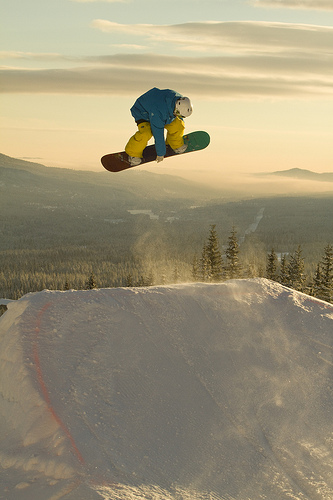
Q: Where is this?
A: This is at the path.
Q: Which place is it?
A: It is a path.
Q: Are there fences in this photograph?
A: No, there are no fences.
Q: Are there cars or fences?
A: No, there are no fences or cars.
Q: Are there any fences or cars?
A: No, there are no fences or cars.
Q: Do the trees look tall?
A: Yes, the trees are tall.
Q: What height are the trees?
A: The trees are tall.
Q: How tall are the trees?
A: The trees are tall.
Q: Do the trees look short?
A: No, the trees are tall.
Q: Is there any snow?
A: Yes, there is snow.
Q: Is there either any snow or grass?
A: Yes, there is snow.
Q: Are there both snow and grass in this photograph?
A: No, there is snow but no grass.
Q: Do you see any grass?
A: No, there is no grass.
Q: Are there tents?
A: No, there are no tents.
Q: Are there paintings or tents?
A: No, there are no tents or paintings.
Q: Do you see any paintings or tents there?
A: No, there are no tents or paintings.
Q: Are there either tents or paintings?
A: No, there are no tents or paintings.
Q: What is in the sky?
A: The clouds are in the sky.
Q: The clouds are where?
A: The clouds are in the sky.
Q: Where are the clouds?
A: The clouds are in the sky.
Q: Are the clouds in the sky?
A: Yes, the clouds are in the sky.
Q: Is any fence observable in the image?
A: No, there are no fences.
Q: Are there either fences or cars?
A: No, there are no fences or cars.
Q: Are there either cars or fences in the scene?
A: No, there are no fences or cars.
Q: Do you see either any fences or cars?
A: No, there are no fences or cars.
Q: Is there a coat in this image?
A: Yes, there is a coat.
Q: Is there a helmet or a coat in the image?
A: Yes, there is a coat.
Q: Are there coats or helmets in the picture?
A: Yes, there is a coat.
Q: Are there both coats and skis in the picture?
A: No, there is a coat but no skis.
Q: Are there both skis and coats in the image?
A: No, there is a coat but no skis.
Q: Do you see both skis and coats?
A: No, there is a coat but no skis.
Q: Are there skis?
A: No, there are no skis.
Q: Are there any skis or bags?
A: No, there are no skis or bags.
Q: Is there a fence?
A: No, there are no fences.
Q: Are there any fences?
A: No, there are no fences.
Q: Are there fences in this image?
A: No, there are no fences.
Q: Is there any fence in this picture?
A: No, there are no fences.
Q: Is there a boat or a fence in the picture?
A: No, there are no fences or boats.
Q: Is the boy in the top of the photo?
A: Yes, the boy is in the top of the image.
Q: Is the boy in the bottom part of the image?
A: No, the boy is in the top of the image.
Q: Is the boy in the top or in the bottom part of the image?
A: The boy is in the top of the image.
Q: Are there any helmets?
A: Yes, there is a helmet.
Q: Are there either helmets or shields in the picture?
A: Yes, there is a helmet.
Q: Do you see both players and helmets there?
A: No, there is a helmet but no players.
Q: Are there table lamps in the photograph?
A: No, there are no table lamps.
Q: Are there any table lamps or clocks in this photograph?
A: No, there are no table lamps or clocks.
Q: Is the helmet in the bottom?
A: No, the helmet is in the top of the image.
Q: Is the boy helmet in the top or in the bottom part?
A: The helmet is in the top of the image.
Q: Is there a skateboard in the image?
A: No, there are no skateboards.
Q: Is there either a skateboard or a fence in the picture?
A: No, there are no skateboards or fences.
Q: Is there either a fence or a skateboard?
A: No, there are no skateboards or fences.